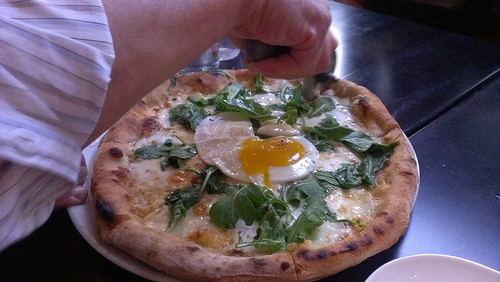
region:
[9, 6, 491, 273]
a scrumptious gourmet pizza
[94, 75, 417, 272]
a restaurant quality pizza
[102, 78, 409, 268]
a personal sized pizza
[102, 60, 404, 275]
a pizza with cheese, arugula, and an egg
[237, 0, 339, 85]
a hand holding a pizza cutter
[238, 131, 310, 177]
a broken egg yolk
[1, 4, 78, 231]
sleeve of a blue and white striped shirt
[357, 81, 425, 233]
golden brown pizza crust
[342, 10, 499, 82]
a shiny wood table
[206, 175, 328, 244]
green arugula leaves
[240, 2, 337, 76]
hand with knife cutting the pizza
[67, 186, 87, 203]
finger on plate holding it steady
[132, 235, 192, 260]
bottom part of pizza crust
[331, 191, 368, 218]
cheese on the pizza pie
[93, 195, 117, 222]
burnt part of crust on the pizza pie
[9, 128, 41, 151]
button hole on shirt of man sleeve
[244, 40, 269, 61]
bottom handle of knife in man hand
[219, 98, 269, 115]
spinich leaf on top of pizza pie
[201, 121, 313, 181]
egg on top of pizza pie in center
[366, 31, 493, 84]
table where plate and pizza pie are on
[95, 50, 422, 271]
pizza on a plate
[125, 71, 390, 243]
green leaves on pizza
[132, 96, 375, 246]
cheese on pizza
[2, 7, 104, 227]
sleeve of person eating pizza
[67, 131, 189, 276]
plate that pizza is on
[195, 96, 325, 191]
egg in the middle of pizza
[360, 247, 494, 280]
edge of white dish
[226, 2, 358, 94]
hand of person cutting pizza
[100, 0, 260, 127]
arm of person cutting pizza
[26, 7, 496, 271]
table that pizza is on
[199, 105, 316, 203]
An egg on a personal pizza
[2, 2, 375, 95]
A man's hand by the pizza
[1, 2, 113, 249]
A pin stripe long sleeve shirt rolled up on a man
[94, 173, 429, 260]
The crust on the pizza is brown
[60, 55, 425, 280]
The plate is white that the pizza is on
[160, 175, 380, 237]
Green vegetables on the pizza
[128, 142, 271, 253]
The cheese on the pizza is white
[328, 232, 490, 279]
The white dish on the side of the pizza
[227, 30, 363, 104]
A man is holding a pizza cutter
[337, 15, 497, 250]
The table is dark cherry brown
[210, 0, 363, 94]
hand holding pizza cutter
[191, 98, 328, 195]
fried egg with broken yolk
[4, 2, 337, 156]
arm with cuff of shirt rolled up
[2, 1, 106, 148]
pinstripes on white material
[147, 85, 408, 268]
cooked egg on bed of spinach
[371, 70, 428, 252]
browned crust on edge of pizza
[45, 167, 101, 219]
finger tip on edge of white plate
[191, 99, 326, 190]
dippy egg with broken yolk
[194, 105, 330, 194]
broken yolk of sunny side up egg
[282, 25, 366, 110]
pizza cutter wheel at edge of pizza